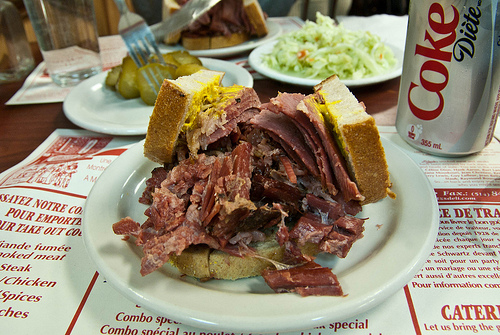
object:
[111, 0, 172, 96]
fork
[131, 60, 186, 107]
food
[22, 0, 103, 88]
glass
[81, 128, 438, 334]
plate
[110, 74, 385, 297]
food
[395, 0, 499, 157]
can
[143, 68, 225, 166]
bread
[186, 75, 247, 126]
mustard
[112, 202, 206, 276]
meat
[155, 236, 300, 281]
bread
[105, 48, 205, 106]
pickles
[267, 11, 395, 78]
lettuce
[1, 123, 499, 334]
mat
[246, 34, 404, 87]
plate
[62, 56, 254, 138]
plate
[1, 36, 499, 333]
table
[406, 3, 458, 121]
coke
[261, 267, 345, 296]
bacon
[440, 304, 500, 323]
cater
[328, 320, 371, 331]
word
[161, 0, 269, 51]
sandwich